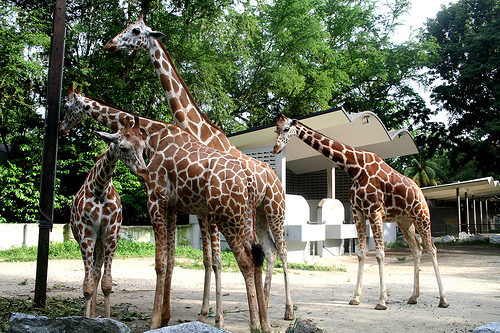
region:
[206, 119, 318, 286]
the giraffe has tail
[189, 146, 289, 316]
the giraffe has tail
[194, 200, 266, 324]
the giraffe has tail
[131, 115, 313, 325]
the giraffe has tail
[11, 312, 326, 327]
rocks in front of giraffes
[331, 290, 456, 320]
hooves of the giraffe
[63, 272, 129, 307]
knees of the giraffe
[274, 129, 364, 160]
giraffes long, spotted, neck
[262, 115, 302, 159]
giraffes fuzzy, spotted, face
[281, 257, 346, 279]
grass growing in pen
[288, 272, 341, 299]
dirt on the ground of pen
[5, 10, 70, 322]
metal pole in pen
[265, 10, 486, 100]
green trees in back of pen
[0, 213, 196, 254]
long wall behind Giraffes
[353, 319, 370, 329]
Small patch of dirt on the ground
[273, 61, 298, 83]
Small section of the green tree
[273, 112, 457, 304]
Giraffe on the far right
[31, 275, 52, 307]
Bottom part of brown pole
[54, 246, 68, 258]
Small patch of green grass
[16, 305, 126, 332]
Huge rock on the ground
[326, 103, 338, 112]
Small part of the black roof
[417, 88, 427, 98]
Small patch of sky in background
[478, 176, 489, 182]
Small part of white roof in background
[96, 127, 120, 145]
Right ear of baby giraffe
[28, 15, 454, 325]
four giraffes in a zoo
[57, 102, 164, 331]
a small giraffe next to big giraffe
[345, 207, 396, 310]
front legs of giraffe are long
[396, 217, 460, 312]
back legs of giraffe are long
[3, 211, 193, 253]
a fence of wood in the pen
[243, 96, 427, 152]
roof of a shelter is white and black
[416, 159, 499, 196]
a shelter on side of pen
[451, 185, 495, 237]
five poles supporting the roof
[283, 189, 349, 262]
feeders on pen of giraffes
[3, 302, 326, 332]
big stones in front of giraffes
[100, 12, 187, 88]
giraffe with a long neck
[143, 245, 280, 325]
legs of the giraffe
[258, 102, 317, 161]
head of the giraffe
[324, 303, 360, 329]
brown dirt below the giraffe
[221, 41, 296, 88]
trees behind the building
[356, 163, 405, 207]
brown spots on the girafe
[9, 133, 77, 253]
pole next to the giraffe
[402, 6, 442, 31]
sky above the trees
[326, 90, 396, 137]
roof next to the giraffes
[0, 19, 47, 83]
leaves on the tree